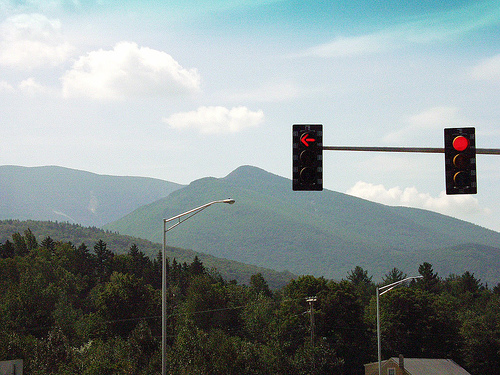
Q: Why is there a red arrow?
A: To indicate not to turn.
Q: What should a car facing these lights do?
A: Stop.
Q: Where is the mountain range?
A: Behind the trees.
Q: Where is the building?
A: At the bottom of the photo.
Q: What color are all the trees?
A: Green.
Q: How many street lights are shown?
A: Two.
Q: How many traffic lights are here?
A: Two.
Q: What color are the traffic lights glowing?
A: Red.